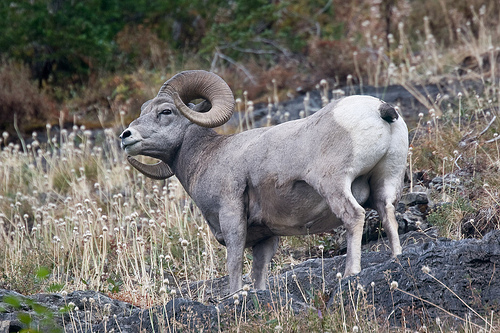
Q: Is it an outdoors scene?
A: Yes, it is outdoors.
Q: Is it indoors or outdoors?
A: It is outdoors.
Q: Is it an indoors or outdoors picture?
A: It is outdoors.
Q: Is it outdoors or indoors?
A: It is outdoors.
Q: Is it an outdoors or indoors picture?
A: It is outdoors.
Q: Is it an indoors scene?
A: No, it is outdoors.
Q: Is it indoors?
A: No, it is outdoors.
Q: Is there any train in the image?
A: No, there are no trains.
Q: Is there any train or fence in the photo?
A: No, there are no trains or fences.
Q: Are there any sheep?
A: Yes, there is a sheep.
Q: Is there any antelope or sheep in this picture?
A: Yes, there is a sheep.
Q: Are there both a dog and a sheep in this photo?
A: No, there is a sheep but no dogs.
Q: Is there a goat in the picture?
A: No, there are no goats.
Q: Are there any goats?
A: No, there are no goats.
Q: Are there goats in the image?
A: No, there are no goats.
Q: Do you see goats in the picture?
A: No, there are no goats.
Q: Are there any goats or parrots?
A: No, there are no goats or parrots.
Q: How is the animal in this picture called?
A: The animal is a sheep.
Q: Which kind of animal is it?
A: The animal is a sheep.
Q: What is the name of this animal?
A: This is a sheep.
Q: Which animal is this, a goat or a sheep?
A: This is a sheep.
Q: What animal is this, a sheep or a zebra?
A: This is a sheep.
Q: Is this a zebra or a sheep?
A: This is a sheep.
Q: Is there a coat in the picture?
A: Yes, there is a coat.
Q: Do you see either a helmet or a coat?
A: Yes, there is a coat.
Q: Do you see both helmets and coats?
A: No, there is a coat but no helmets.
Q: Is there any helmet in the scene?
A: No, there are no helmets.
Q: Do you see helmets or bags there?
A: No, there are no helmets or bags.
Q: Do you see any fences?
A: No, there are no fences.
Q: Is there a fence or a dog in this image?
A: No, there are no fences or dogs.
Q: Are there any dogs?
A: No, there are no dogs.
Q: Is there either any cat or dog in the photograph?
A: No, there are no dogs or cats.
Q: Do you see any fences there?
A: No, there are no fences.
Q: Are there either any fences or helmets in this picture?
A: No, there are no fences or helmets.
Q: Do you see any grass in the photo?
A: Yes, there is grass.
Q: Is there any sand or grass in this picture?
A: Yes, there is grass.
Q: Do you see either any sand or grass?
A: Yes, there is grass.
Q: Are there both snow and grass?
A: No, there is grass but no snow.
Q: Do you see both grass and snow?
A: No, there is grass but no snow.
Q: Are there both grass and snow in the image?
A: No, there is grass but no snow.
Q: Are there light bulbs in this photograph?
A: No, there are no light bulbs.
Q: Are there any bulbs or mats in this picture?
A: No, there are no bulbs or mats.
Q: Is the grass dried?
A: Yes, the grass is dried.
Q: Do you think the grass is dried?
A: Yes, the grass is dried.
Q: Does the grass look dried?
A: Yes, the grass is dried.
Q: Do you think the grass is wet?
A: No, the grass is dried.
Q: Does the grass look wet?
A: No, the grass is dried.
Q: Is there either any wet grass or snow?
A: No, there is grass but it is dried.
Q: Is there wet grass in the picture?
A: No, there is grass but it is dried.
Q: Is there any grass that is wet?
A: No, there is grass but it is dried.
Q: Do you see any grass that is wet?
A: No, there is grass but it is dried.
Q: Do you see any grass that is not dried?
A: No, there is grass but it is dried.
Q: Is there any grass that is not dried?
A: No, there is grass but it is dried.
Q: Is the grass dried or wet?
A: The grass is dried.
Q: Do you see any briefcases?
A: No, there are no briefcases.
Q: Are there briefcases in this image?
A: No, there are no briefcases.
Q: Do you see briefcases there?
A: No, there are no briefcases.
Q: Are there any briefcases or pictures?
A: No, there are no briefcases or pictures.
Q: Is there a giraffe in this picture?
A: No, there are no giraffes.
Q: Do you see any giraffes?
A: No, there are no giraffes.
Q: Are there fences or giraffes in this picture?
A: No, there are no giraffes or fences.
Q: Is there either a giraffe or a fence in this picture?
A: No, there are no giraffes or fences.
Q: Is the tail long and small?
A: No, the tail is small but short.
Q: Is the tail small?
A: Yes, the tail is small.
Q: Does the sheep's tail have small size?
A: Yes, the tail is small.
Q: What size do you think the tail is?
A: The tail is small.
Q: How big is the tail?
A: The tail is small.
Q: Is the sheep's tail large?
A: No, the tail is small.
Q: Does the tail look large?
A: No, the tail is small.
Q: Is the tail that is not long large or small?
A: The tail is small.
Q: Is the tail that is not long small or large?
A: The tail is small.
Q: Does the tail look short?
A: Yes, the tail is short.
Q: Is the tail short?
A: Yes, the tail is short.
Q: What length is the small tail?
A: The tail is short.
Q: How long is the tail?
A: The tail is short.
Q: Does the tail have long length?
A: No, the tail is short.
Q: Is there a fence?
A: No, there are no fences.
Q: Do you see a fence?
A: No, there are no fences.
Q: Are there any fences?
A: No, there are no fences.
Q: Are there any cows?
A: No, there are no cows.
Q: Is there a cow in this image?
A: No, there are no cows.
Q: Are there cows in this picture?
A: No, there are no cows.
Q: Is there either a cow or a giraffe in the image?
A: No, there are no cows or giraffes.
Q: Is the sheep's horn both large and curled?
A: Yes, the horn is large and curled.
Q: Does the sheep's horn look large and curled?
A: Yes, the horn is large and curled.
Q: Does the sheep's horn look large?
A: Yes, the horn is large.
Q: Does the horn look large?
A: Yes, the horn is large.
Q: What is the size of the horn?
A: The horn is large.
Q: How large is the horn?
A: The horn is large.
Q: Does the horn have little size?
A: No, the horn is large.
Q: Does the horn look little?
A: No, the horn is large.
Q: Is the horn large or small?
A: The horn is large.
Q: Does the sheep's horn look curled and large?
A: Yes, the horn is curled and large.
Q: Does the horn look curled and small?
A: No, the horn is curled but large.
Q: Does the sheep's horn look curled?
A: Yes, the horn is curled.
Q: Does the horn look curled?
A: Yes, the horn is curled.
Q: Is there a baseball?
A: No, there are no baseballs.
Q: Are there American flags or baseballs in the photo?
A: No, there are no baseballs or American flags.